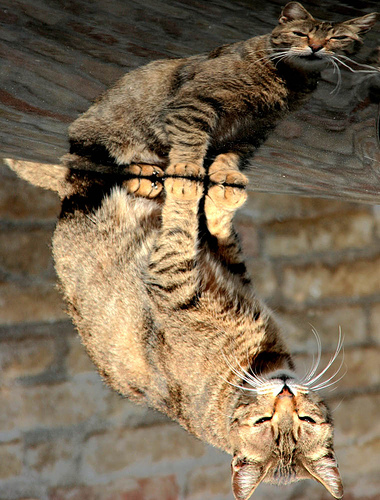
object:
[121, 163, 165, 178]
paw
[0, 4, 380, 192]
reflection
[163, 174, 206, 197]
paw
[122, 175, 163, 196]
paw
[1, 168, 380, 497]
water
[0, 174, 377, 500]
reflection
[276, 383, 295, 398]
nose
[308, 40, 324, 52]
nose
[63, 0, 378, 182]
cat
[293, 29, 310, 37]
eyes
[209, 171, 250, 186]
paw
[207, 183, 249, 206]
paw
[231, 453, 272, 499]
ear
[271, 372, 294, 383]
mouth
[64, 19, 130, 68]
wall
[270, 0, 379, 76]
head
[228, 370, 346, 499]
head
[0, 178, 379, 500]
wall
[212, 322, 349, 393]
whiskers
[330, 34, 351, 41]
eyes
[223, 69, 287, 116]
chest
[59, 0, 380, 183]
reflection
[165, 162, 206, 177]
claw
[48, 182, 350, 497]
cat